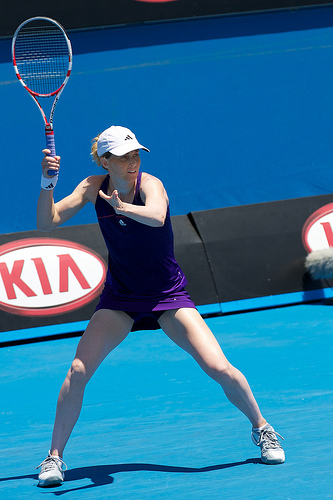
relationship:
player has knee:
[35, 124, 285, 489] [24, 117, 289, 486]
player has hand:
[35, 124, 285, 489] [35, 148, 64, 184]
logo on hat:
[124, 134, 133, 141] [96, 125, 150, 159]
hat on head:
[96, 125, 150, 159] [93, 125, 142, 181]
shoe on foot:
[251, 418, 286, 465] [250, 425, 285, 463]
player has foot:
[35, 124, 285, 489] [250, 425, 285, 463]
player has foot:
[35, 124, 285, 489] [33, 451, 68, 487]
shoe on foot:
[35, 456, 65, 486] [33, 451, 68, 487]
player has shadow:
[35, 124, 285, 489] [1, 457, 264, 497]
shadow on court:
[1, 457, 264, 497] [261, 310, 332, 403]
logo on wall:
[1, 237, 108, 320] [8, 58, 327, 289]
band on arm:
[40, 173, 58, 191] [34, 145, 98, 227]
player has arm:
[35, 124, 285, 489] [34, 145, 98, 227]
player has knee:
[35, 124, 285, 489] [206, 357, 241, 383]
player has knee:
[35, 124, 285, 489] [63, 359, 91, 387]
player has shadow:
[35, 127, 301, 490] [1, 457, 264, 497]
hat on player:
[96, 125, 150, 159] [35, 124, 285, 489]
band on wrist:
[40, 173, 58, 191] [37, 171, 60, 190]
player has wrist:
[35, 124, 285, 489] [37, 171, 60, 190]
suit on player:
[84, 176, 197, 325] [35, 124, 285, 489]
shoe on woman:
[33, 449, 67, 487] [28, 90, 316, 463]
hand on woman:
[40, 148, 61, 178] [7, 116, 313, 496]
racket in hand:
[3, 7, 99, 167] [40, 148, 61, 178]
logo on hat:
[124, 128, 159, 144] [94, 119, 169, 170]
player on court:
[35, 124, 285, 489] [26, 315, 328, 464]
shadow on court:
[59, 417, 309, 482] [26, 315, 328, 464]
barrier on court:
[0, 193, 333, 334] [26, 325, 327, 489]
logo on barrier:
[0, 235, 108, 320] [0, 193, 333, 334]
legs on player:
[61, 292, 288, 440] [37, 124, 217, 397]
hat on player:
[79, 127, 187, 173] [35, 124, 285, 489]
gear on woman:
[79, 181, 212, 295] [44, 127, 247, 435]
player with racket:
[35, 124, 285, 489] [0, 12, 82, 153]